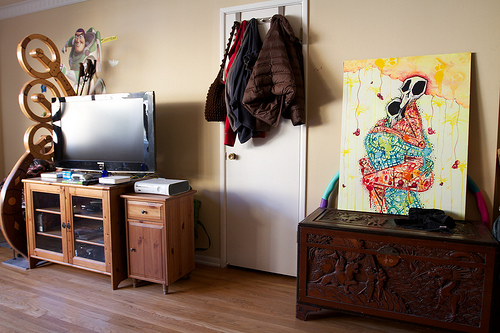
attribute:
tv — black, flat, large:
[57, 98, 151, 164]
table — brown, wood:
[39, 183, 115, 223]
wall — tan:
[153, 21, 165, 33]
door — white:
[260, 150, 275, 170]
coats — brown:
[236, 39, 290, 90]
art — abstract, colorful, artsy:
[381, 94, 455, 150]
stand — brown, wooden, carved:
[327, 250, 385, 276]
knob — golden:
[228, 153, 236, 159]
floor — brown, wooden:
[218, 294, 236, 304]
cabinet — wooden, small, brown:
[129, 203, 174, 268]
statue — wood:
[34, 51, 43, 68]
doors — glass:
[54, 217, 77, 238]